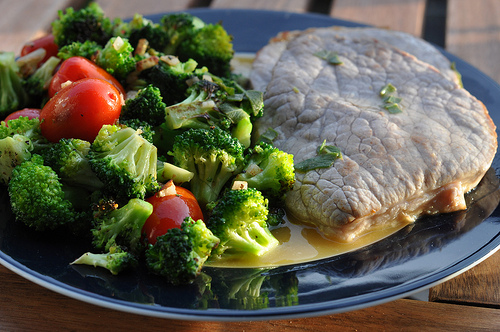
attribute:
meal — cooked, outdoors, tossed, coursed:
[0, 3, 498, 285]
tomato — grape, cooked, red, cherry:
[39, 81, 122, 141]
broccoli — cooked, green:
[120, 84, 165, 127]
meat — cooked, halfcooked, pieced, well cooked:
[440, 186, 469, 216]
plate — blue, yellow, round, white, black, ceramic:
[1, 9, 498, 321]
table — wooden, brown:
[1, 2, 499, 329]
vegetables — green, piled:
[1, 3, 298, 284]